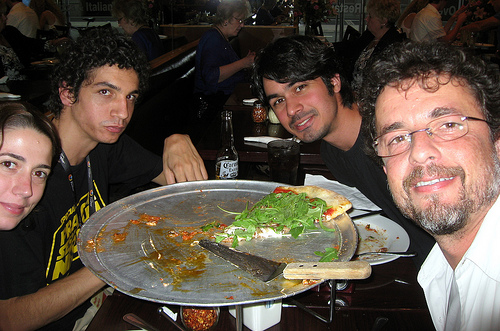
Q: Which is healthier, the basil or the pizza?
A: The basil is healthier than the pizza.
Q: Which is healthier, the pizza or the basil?
A: The basil is healthier than the pizza.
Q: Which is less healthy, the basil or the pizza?
A: The pizza is less healthy than the basil.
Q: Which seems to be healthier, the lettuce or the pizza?
A: The lettuce is healthier than the pizza.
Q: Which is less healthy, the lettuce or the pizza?
A: The pizza is less healthy than the lettuce.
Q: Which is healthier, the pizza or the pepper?
A: The pepper is healthier than the pizza.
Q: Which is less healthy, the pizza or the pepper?
A: The pizza is less healthy than the pepper.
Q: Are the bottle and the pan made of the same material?
A: No, the bottle is made of glass and the pan is made of metal.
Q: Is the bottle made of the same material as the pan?
A: No, the bottle is made of glass and the pan is made of metal.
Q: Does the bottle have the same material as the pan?
A: No, the bottle is made of glass and the pan is made of metal.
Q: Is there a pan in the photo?
A: Yes, there is a pan.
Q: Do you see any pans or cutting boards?
A: Yes, there is a pan.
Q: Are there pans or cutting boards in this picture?
A: Yes, there is a pan.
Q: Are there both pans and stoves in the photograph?
A: No, there is a pan but no stoves.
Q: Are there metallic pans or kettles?
A: Yes, there is a metal pan.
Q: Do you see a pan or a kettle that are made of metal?
A: Yes, the pan is made of metal.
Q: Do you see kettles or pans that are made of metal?
A: Yes, the pan is made of metal.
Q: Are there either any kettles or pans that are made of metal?
A: Yes, the pan is made of metal.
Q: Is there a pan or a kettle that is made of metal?
A: Yes, the pan is made of metal.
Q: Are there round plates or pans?
A: Yes, there is a round pan.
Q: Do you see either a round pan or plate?
A: Yes, there is a round pan.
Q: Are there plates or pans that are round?
A: Yes, the pan is round.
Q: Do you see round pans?
A: Yes, there is a round pan.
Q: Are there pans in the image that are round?
A: Yes, there is a pan that is round.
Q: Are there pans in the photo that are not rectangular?
A: Yes, there is a round pan.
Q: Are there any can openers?
A: No, there are no can openers.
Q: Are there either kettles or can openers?
A: No, there are no can openers or kettles.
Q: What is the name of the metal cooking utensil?
A: The cooking utensil is a pan.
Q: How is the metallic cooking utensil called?
A: The cooking utensil is a pan.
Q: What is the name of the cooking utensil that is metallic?
A: The cooking utensil is a pan.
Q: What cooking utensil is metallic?
A: The cooking utensil is a pan.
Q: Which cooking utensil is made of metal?
A: The cooking utensil is a pan.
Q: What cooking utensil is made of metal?
A: The cooking utensil is a pan.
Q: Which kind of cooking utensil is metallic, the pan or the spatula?
A: The pan is metallic.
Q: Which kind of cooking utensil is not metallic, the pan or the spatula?
A: The spatula is not metallic.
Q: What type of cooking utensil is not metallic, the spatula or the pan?
A: The spatula is not metallic.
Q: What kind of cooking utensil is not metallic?
A: The cooking utensil is a spatula.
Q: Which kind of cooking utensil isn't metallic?
A: The cooking utensil is a spatula.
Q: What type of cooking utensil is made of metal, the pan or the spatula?
A: The pan is made of metal.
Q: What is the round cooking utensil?
A: The cooking utensil is a pan.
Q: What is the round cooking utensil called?
A: The cooking utensil is a pan.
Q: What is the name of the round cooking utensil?
A: The cooking utensil is a pan.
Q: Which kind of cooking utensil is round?
A: The cooking utensil is a pan.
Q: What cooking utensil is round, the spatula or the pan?
A: The pan is round.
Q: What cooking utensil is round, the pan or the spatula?
A: The pan is round.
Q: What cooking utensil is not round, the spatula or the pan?
A: The spatula is not round.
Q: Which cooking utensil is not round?
A: The cooking utensil is a spatula.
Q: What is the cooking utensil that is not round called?
A: The cooking utensil is a spatula.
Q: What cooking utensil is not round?
A: The cooking utensil is a spatula.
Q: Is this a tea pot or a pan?
A: This is a pan.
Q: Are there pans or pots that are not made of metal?
A: No, there is a pan but it is made of metal.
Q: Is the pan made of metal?
A: Yes, the pan is made of metal.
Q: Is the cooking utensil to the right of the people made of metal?
A: Yes, the pan is made of metal.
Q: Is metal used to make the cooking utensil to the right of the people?
A: Yes, the pan is made of metal.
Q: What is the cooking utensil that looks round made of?
A: The pan is made of metal.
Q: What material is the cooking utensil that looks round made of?
A: The pan is made of metal.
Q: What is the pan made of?
A: The pan is made of metal.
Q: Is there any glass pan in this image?
A: No, there is a pan but it is made of metal.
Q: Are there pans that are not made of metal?
A: No, there is a pan but it is made of metal.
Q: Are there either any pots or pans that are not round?
A: No, there is a pan but it is round.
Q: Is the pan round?
A: Yes, the pan is round.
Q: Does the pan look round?
A: Yes, the pan is round.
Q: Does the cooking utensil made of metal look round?
A: Yes, the pan is round.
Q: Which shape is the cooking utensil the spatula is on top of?
A: The pan is round.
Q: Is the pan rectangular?
A: No, the pan is round.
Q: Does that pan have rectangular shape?
A: No, the pan is round.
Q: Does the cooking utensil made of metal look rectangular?
A: No, the pan is round.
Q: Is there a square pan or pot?
A: No, there is a pan but it is round.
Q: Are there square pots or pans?
A: No, there is a pan but it is round.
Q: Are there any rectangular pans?
A: No, there is a pan but it is round.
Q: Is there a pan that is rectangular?
A: No, there is a pan but it is round.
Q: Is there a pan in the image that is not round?
A: No, there is a pan but it is round.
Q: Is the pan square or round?
A: The pan is round.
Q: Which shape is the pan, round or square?
A: The pan is round.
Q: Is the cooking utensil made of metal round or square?
A: The pan is round.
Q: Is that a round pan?
A: Yes, that is a round pan.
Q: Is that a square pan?
A: No, that is a round pan.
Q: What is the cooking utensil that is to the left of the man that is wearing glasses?
A: The cooking utensil is a pan.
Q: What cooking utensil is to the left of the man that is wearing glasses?
A: The cooking utensil is a pan.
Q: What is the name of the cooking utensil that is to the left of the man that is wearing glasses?
A: The cooking utensil is a pan.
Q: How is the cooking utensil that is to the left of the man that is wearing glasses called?
A: The cooking utensil is a pan.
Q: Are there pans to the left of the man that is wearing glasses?
A: Yes, there is a pan to the left of the man.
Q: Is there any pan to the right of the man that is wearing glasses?
A: No, the pan is to the left of the man.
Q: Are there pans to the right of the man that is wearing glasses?
A: No, the pan is to the left of the man.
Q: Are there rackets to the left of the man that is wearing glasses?
A: No, there is a pan to the left of the man.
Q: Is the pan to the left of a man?
A: Yes, the pan is to the left of a man.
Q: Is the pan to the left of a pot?
A: No, the pan is to the left of a man.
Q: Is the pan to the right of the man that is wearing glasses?
A: No, the pan is to the left of the man.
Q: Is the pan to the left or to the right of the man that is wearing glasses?
A: The pan is to the left of the man.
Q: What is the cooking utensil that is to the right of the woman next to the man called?
A: The cooking utensil is a pan.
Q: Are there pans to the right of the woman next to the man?
A: Yes, there is a pan to the right of the woman.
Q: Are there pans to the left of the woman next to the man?
A: No, the pan is to the right of the woman.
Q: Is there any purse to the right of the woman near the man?
A: No, there is a pan to the right of the woman.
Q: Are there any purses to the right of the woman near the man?
A: No, there is a pan to the right of the woman.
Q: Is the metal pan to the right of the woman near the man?
A: Yes, the pan is to the right of the woman.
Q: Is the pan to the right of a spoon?
A: No, the pan is to the right of the woman.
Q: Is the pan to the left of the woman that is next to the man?
A: No, the pan is to the right of the woman.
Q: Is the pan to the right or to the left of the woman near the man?
A: The pan is to the right of the woman.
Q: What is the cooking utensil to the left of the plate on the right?
A: The cooking utensil is a pan.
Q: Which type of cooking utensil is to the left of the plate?
A: The cooking utensil is a pan.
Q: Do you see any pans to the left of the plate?
A: Yes, there is a pan to the left of the plate.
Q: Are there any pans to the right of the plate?
A: No, the pan is to the left of the plate.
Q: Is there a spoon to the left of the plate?
A: No, there is a pan to the left of the plate.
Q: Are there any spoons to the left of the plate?
A: No, there is a pan to the left of the plate.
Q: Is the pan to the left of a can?
A: No, the pan is to the left of the plate.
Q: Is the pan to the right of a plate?
A: No, the pan is to the left of a plate.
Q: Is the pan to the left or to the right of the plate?
A: The pan is to the left of the plate.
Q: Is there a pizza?
A: Yes, there is a pizza.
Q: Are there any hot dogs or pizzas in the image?
A: Yes, there is a pizza.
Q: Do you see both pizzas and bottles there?
A: Yes, there are both a pizza and a bottle.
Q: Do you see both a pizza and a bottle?
A: Yes, there are both a pizza and a bottle.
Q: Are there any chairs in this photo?
A: No, there are no chairs.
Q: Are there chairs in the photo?
A: No, there are no chairs.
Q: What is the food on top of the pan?
A: The food is a pizza.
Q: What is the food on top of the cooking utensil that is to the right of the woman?
A: The food is a pizza.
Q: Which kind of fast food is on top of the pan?
A: The food is a pizza.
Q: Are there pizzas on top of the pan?
A: Yes, there is a pizza on top of the pan.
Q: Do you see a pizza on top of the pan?
A: Yes, there is a pizza on top of the pan.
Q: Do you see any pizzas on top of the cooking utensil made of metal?
A: Yes, there is a pizza on top of the pan.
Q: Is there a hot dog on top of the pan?
A: No, there is a pizza on top of the pan.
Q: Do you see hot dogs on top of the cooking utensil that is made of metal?
A: No, there is a pizza on top of the pan.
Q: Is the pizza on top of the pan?
A: Yes, the pizza is on top of the pan.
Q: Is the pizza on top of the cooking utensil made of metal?
A: Yes, the pizza is on top of the pan.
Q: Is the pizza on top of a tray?
A: No, the pizza is on top of the pan.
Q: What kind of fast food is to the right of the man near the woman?
A: The food is a pizza.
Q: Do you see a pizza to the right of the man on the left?
A: Yes, there is a pizza to the right of the man.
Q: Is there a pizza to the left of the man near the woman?
A: No, the pizza is to the right of the man.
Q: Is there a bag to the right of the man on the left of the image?
A: No, there is a pizza to the right of the man.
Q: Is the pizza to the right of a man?
A: Yes, the pizza is to the right of a man.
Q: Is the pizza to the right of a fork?
A: No, the pizza is to the right of a man.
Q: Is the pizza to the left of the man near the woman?
A: No, the pizza is to the right of the man.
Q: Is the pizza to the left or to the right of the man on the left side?
A: The pizza is to the right of the man.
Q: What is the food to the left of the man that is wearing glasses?
A: The food is a pizza.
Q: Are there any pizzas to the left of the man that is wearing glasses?
A: Yes, there is a pizza to the left of the man.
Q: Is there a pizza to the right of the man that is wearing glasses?
A: No, the pizza is to the left of the man.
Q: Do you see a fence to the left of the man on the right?
A: No, there is a pizza to the left of the man.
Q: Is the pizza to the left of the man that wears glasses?
A: Yes, the pizza is to the left of the man.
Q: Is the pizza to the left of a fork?
A: No, the pizza is to the left of the man.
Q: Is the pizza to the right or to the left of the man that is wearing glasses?
A: The pizza is to the left of the man.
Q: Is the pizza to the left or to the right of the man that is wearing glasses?
A: The pizza is to the left of the man.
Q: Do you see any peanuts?
A: No, there are no peanuts.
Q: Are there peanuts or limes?
A: No, there are no peanuts or limes.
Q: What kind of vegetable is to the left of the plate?
A: The vegetable is basil.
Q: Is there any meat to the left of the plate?
A: No, there is basil to the left of the plate.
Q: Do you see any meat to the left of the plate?
A: No, there is basil to the left of the plate.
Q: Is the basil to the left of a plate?
A: Yes, the basil is to the left of a plate.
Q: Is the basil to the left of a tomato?
A: No, the basil is to the left of a plate.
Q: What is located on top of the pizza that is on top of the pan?
A: The basil is on top of the pizza.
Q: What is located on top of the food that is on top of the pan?
A: The basil is on top of the pizza.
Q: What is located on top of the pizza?
A: The basil is on top of the pizza.